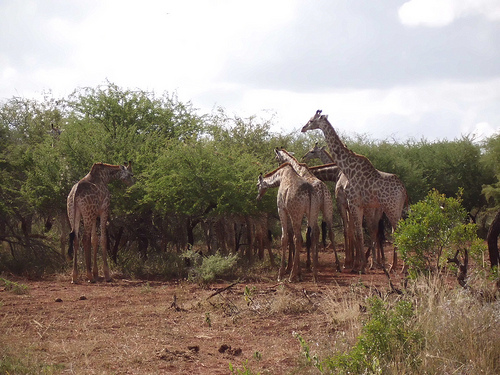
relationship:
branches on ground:
[208, 281, 248, 316] [207, 295, 282, 328]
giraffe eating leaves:
[62, 156, 138, 291] [0, 79, 499, 215]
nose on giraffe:
[300, 126, 310, 133] [297, 104, 408, 277]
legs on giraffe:
[67, 215, 108, 283] [61, 158, 131, 285]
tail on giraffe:
[65, 196, 77, 260] [64, 155, 125, 284]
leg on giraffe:
[86, 218, 100, 281] [61, 158, 131, 285]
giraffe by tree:
[66, 162, 136, 286] [57, 79, 179, 191]